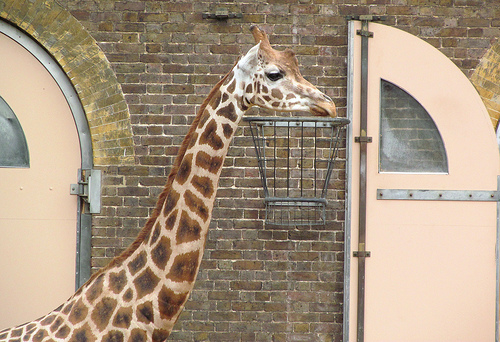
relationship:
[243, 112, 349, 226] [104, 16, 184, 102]
basket on wall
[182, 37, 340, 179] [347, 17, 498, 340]
giraffe near door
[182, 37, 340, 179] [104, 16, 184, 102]
giraffe near wall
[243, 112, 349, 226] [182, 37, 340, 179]
basket near giraffe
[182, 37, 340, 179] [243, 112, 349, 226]
giraffe next to basket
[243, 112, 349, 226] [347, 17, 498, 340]
basket near door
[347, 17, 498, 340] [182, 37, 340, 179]
door next to giraffe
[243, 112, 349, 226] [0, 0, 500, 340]
basket on wall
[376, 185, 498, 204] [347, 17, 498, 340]
metal strip on door